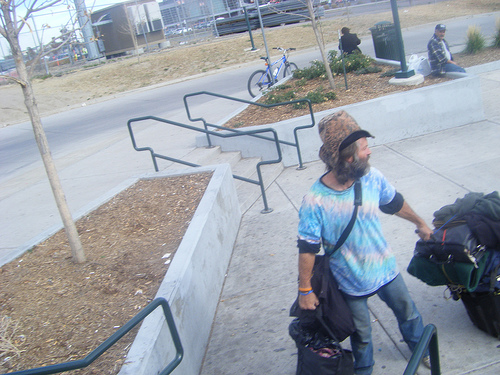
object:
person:
[336, 24, 363, 57]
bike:
[244, 46, 297, 97]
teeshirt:
[302, 165, 398, 308]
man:
[295, 109, 435, 374]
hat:
[316, 113, 371, 167]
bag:
[286, 266, 353, 352]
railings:
[125, 115, 285, 208]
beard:
[338, 145, 370, 182]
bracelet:
[295, 291, 316, 298]